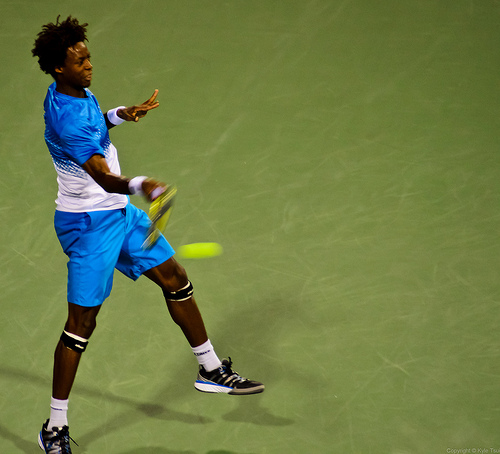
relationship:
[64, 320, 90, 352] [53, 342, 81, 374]
band on knee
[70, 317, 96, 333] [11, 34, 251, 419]
knee of player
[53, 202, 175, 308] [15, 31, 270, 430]
drawers of player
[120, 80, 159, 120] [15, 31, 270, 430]
hand of player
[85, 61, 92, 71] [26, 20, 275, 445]
nose of player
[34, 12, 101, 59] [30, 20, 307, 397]
hair of player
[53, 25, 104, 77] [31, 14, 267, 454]
head of man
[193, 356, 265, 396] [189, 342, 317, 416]
shoe on foot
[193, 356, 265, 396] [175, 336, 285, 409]
shoe on foot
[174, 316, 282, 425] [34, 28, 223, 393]
sock on man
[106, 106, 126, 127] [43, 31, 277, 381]
band on man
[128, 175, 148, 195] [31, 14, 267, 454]
band on man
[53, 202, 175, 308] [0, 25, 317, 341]
drawers on player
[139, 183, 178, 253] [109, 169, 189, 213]
bat in hand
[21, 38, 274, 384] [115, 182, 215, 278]
man holding bat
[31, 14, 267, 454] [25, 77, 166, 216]
man wearing shirt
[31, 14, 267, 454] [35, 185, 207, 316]
man wearing drawers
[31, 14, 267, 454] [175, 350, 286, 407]
man wearing shoe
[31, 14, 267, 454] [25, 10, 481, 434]
man on court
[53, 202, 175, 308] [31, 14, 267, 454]
drawers on man